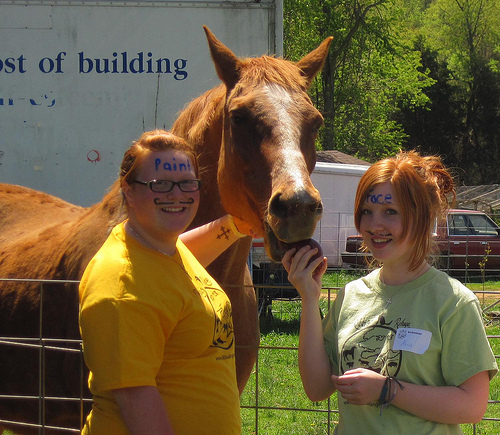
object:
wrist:
[229, 214, 248, 236]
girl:
[280, 145, 497, 435]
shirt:
[320, 266, 498, 435]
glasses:
[135, 179, 201, 193]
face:
[141, 147, 198, 230]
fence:
[0, 278, 500, 435]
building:
[308, 148, 374, 268]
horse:
[0, 24, 333, 435]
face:
[360, 184, 408, 258]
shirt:
[76, 217, 241, 435]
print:
[201, 287, 236, 351]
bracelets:
[380, 381, 398, 408]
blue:
[367, 189, 392, 204]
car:
[340, 209, 500, 275]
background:
[326, 43, 500, 257]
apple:
[290, 237, 324, 273]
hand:
[281, 245, 327, 298]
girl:
[74, 127, 247, 435]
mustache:
[154, 197, 195, 204]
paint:
[155, 158, 191, 172]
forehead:
[146, 152, 195, 177]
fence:
[249, 214, 500, 289]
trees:
[277, 0, 498, 160]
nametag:
[393, 327, 433, 354]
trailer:
[315, 236, 369, 270]